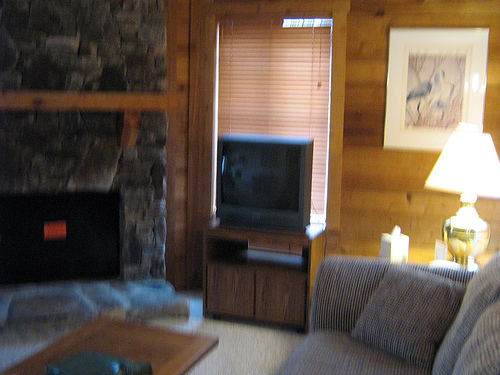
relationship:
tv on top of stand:
[215, 130, 313, 233] [205, 220, 327, 332]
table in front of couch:
[3, 315, 219, 372] [269, 254, 499, 371]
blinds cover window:
[219, 17, 327, 216] [199, 4, 350, 233]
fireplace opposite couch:
[1, 2, 189, 320] [269, 254, 499, 371]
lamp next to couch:
[425, 131, 499, 273] [269, 254, 499, 371]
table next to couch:
[3, 315, 219, 372] [269, 254, 499, 371]